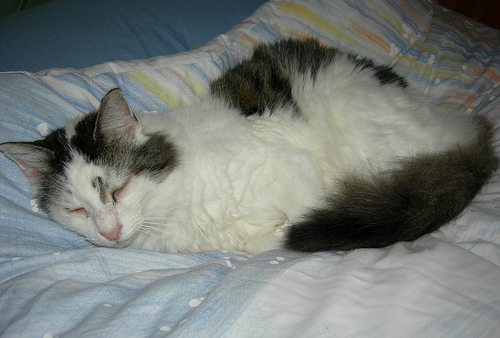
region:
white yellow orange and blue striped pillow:
[2, 1, 499, 173]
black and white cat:
[2, 40, 497, 255]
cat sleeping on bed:
[6, 33, 496, 255]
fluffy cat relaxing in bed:
[3, 38, 492, 254]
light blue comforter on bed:
[1, 1, 270, 68]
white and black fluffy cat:
[3, 33, 499, 259]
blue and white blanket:
[6, 68, 499, 335]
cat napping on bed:
[8, 37, 499, 250]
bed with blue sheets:
[2, 1, 498, 336]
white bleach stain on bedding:
[189, 295, 207, 310]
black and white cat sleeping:
[31, 78, 463, 233]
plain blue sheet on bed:
[8, 12, 293, 69]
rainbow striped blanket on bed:
[16, 40, 450, 293]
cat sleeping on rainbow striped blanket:
[9, 57, 499, 326]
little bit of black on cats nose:
[76, 147, 139, 254]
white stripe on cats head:
[9, 99, 140, 184]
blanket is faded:
[25, 113, 457, 335]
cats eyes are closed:
[9, 118, 216, 254]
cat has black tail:
[273, 65, 497, 298]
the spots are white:
[191, 295, 206, 317]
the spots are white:
[161, 320, 174, 333]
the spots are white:
[273, 247, 292, 277]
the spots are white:
[193, 295, 217, 317]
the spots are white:
[186, 302, 201, 308]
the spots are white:
[180, 293, 207, 304]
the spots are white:
[153, 316, 170, 336]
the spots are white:
[276, 255, 283, 262]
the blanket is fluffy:
[355, 252, 383, 294]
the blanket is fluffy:
[255, 290, 276, 305]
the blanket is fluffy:
[279, 306, 295, 311]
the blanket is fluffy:
[282, 311, 299, 322]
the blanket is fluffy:
[294, 306, 325, 323]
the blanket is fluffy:
[166, 298, 184, 308]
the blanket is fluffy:
[301, 307, 317, 314]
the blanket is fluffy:
[377, 295, 408, 317]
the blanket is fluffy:
[333, 291, 353, 313]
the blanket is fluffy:
[323, 299, 340, 309]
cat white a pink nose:
[82, 211, 152, 278]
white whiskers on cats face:
[45, 201, 195, 274]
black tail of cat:
[300, 143, 479, 253]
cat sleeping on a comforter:
[19, 40, 474, 292]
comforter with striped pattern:
[399, 18, 469, 85]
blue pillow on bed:
[39, 6, 143, 64]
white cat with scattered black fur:
[40, 40, 439, 261]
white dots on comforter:
[182, 263, 244, 320]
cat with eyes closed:
[35, 65, 162, 253]